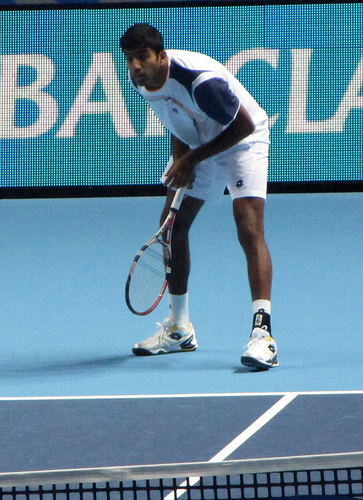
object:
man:
[119, 23, 280, 368]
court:
[22, 229, 94, 330]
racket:
[125, 186, 189, 315]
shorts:
[160, 121, 273, 203]